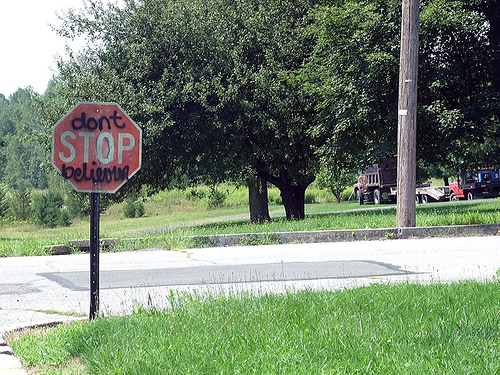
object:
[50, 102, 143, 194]
sign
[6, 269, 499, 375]
grass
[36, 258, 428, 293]
patch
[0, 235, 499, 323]
road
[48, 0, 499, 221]
tree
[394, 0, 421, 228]
pole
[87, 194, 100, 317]
pole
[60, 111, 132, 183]
graffiti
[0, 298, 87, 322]
crack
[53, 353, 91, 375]
dirt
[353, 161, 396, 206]
truck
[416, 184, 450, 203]
trailer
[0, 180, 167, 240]
evergreens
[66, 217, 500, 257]
curb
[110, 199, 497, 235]
road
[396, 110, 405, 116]
white sticker